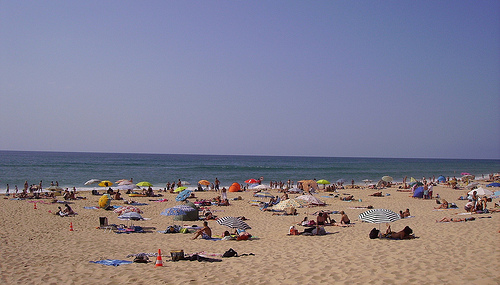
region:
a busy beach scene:
[12, 107, 487, 277]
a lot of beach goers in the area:
[29, 162, 481, 257]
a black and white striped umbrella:
[362, 202, 409, 245]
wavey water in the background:
[46, 146, 460, 176]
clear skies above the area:
[19, 26, 451, 136]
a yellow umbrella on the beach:
[124, 172, 154, 189]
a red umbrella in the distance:
[237, 173, 264, 184]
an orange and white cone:
[149, 237, 174, 276]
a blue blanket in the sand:
[92, 247, 132, 279]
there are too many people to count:
[75, 176, 498, 234]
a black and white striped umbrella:
[357, 205, 399, 227]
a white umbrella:
[469, 186, 491, 197]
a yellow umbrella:
[97, 191, 107, 209]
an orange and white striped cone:
[153, 247, 165, 268]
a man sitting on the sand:
[192, 217, 213, 244]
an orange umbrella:
[196, 176, 210, 186]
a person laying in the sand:
[435, 210, 470, 226]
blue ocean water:
[0, 149, 498, 187]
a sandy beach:
[0, 174, 498, 284]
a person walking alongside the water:
[4, 178, 11, 196]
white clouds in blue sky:
[36, 26, 92, 72]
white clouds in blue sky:
[311, 79, 351, 110]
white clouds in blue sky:
[396, 30, 443, 68]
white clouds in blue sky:
[178, 33, 271, 76]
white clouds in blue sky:
[75, 17, 124, 62]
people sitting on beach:
[170, 210, 219, 238]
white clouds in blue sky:
[4, 41, 55, 81]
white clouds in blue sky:
[155, 77, 185, 117]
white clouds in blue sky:
[228, 42, 280, 104]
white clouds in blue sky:
[76, 47, 123, 101]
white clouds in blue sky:
[45, 46, 84, 69]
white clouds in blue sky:
[260, 34, 307, 75]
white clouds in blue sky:
[325, 52, 355, 99]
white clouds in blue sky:
[400, 63, 454, 118]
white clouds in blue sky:
[172, 47, 238, 116]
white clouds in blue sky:
[267, 64, 317, 114]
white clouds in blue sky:
[57, 16, 89, 57]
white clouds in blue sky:
[112, 96, 179, 138]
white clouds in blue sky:
[137, 36, 227, 107]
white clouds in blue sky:
[83, 97, 133, 136]